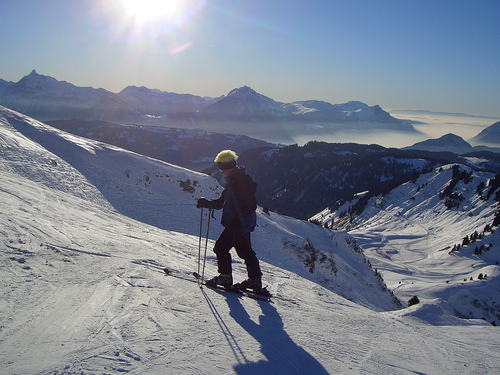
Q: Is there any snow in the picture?
A: Yes, there is snow.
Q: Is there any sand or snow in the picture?
A: Yes, there is snow.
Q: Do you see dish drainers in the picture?
A: No, there are no dish drainers.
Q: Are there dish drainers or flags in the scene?
A: No, there are no dish drainers or flags.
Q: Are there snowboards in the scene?
A: Yes, there is a snowboard.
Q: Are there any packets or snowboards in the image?
A: Yes, there is a snowboard.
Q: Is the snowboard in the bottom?
A: Yes, the snowboard is in the bottom of the image.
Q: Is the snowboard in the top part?
A: No, the snowboard is in the bottom of the image.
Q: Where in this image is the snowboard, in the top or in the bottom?
A: The snowboard is in the bottom of the image.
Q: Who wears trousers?
A: The man wears trousers.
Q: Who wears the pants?
A: The man wears trousers.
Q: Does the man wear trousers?
A: Yes, the man wears trousers.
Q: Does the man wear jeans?
A: No, the man wears trousers.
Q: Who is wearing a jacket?
A: The man is wearing a jacket.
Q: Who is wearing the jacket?
A: The man is wearing a jacket.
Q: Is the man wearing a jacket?
A: Yes, the man is wearing a jacket.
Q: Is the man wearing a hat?
A: No, the man is wearing a jacket.